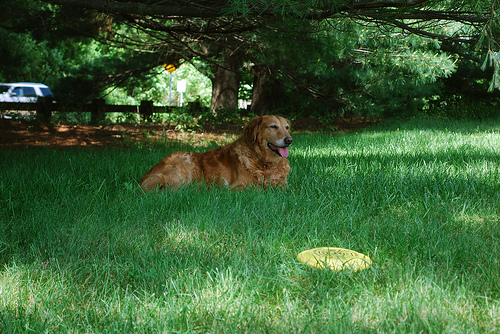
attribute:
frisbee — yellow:
[294, 240, 380, 273]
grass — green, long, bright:
[7, 141, 500, 330]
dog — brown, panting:
[128, 112, 298, 195]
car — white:
[0, 80, 60, 121]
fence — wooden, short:
[1, 92, 319, 124]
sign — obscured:
[161, 49, 187, 109]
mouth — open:
[266, 138, 292, 160]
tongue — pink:
[278, 147, 289, 158]